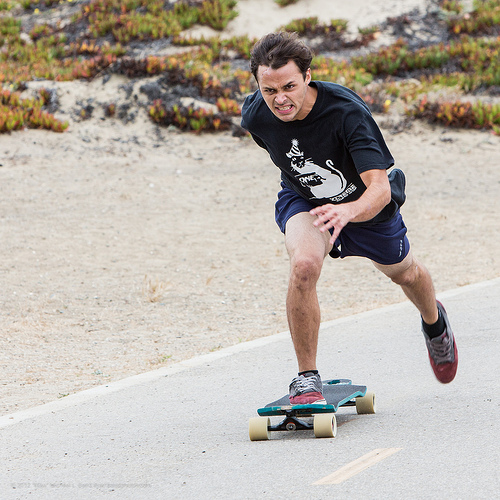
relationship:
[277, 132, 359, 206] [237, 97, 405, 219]
logo on shirt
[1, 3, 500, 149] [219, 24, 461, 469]
grass behind man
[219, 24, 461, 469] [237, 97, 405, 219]
man in shirt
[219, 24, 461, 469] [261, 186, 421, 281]
man in shorts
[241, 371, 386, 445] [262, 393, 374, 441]
board has tires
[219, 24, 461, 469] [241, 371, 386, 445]
man on board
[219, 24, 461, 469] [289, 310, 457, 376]
man has socks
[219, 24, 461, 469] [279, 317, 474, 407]
man has shoes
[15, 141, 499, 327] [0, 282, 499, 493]
dirt near road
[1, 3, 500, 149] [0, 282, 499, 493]
grass near road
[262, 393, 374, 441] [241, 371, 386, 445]
tires on board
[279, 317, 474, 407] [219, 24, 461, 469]
shoes on man